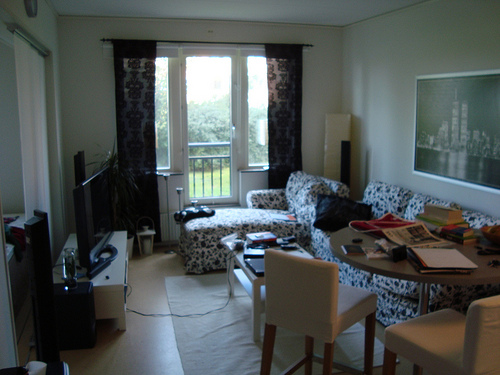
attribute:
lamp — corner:
[315, 107, 350, 179]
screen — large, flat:
[69, 151, 124, 273]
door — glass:
[186, 50, 238, 235]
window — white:
[3, 11, 62, 257]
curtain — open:
[13, 36, 52, 268]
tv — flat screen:
[58, 165, 137, 284]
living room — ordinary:
[0, 1, 499, 373]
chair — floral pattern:
[176, 168, 352, 276]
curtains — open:
[110, 38, 162, 242]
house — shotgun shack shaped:
[2, 0, 497, 373]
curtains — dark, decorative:
[103, 34, 168, 264]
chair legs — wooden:
[275, 239, 495, 360]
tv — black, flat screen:
[64, 166, 149, 278]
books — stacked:
[375, 205, 496, 271]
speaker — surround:
[24, 209, 69, 374]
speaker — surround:
[70, 145, 84, 187]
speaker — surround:
[339, 137, 351, 189]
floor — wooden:
[128, 279, 200, 361]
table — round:
[344, 202, 499, 315]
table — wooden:
[321, 212, 499, 312]